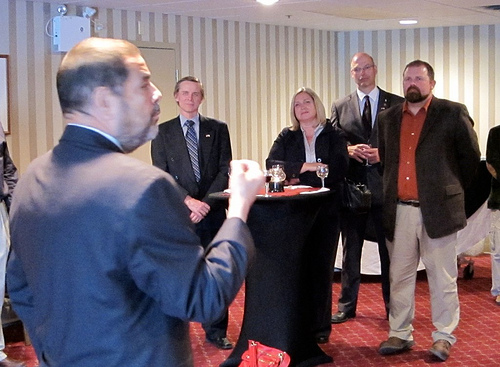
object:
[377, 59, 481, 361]
guy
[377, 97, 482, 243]
brown blazer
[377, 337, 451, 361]
shoe shoe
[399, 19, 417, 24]
light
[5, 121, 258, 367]
suit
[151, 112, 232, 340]
suit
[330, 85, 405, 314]
suit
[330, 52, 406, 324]
man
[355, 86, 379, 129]
shirt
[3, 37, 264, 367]
man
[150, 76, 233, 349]
man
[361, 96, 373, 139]
tie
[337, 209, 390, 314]
pants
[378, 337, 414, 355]
loafers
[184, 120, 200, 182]
tie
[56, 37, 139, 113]
hair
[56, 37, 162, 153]
head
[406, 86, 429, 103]
beard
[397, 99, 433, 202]
shirt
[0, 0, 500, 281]
buildings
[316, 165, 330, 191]
glass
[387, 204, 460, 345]
pants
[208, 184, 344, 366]
table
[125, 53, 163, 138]
man's face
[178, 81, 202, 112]
man's face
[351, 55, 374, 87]
man's face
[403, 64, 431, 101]
man's face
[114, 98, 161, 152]
dark beard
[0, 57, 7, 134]
picture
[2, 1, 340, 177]
wall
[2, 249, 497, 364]
carpet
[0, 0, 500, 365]
room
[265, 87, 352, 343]
person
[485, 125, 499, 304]
man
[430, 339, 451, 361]
shoe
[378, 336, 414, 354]
shoe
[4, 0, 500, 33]
ceiling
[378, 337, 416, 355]
foot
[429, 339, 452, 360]
foot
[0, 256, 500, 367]
floor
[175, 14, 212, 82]
stripe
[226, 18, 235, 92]
stripe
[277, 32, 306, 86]
stripe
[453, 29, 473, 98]
stripe